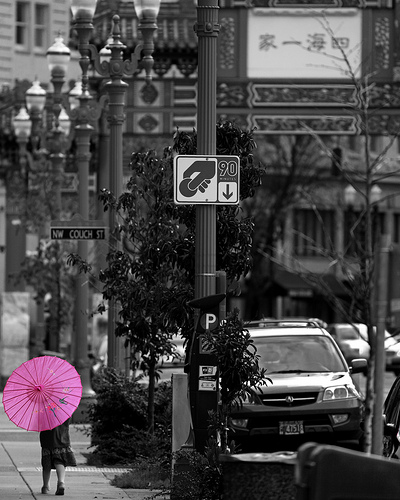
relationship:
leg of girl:
[43, 451, 68, 499] [38, 404, 78, 498]